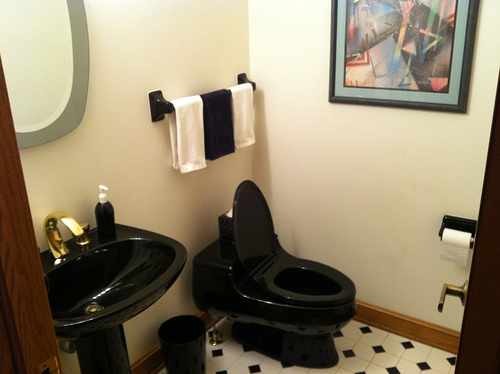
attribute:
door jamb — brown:
[0, 60, 62, 371]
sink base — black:
[75, 325, 131, 372]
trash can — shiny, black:
[158, 314, 208, 372]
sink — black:
[40, 214, 186, 373]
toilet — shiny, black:
[193, 180, 356, 368]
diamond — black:
[375, 345, 385, 354]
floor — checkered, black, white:
[159, 315, 457, 371]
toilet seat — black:
[255, 255, 356, 305]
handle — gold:
[438, 284, 468, 314]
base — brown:
[131, 300, 462, 371]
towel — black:
[202, 89, 237, 159]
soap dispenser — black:
[96, 185, 114, 238]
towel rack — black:
[150, 73, 265, 123]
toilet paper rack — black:
[439, 216, 477, 247]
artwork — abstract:
[329, 0, 481, 112]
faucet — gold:
[45, 213, 88, 264]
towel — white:
[229, 83, 258, 150]